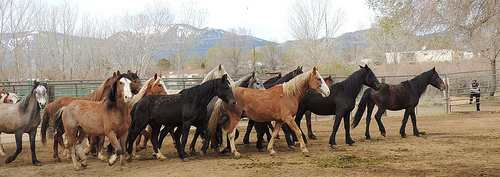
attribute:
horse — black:
[333, 60, 369, 120]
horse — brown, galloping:
[93, 84, 132, 136]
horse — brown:
[254, 64, 325, 145]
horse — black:
[406, 67, 442, 135]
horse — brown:
[54, 83, 111, 108]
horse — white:
[247, 57, 269, 89]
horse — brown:
[145, 74, 167, 96]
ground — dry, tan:
[144, 112, 491, 148]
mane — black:
[416, 74, 432, 90]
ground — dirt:
[168, 153, 240, 175]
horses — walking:
[42, 68, 482, 148]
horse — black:
[265, 73, 298, 85]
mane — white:
[132, 79, 152, 105]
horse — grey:
[0, 77, 42, 133]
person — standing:
[465, 69, 499, 109]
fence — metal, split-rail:
[445, 68, 470, 122]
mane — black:
[109, 73, 123, 106]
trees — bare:
[289, 11, 343, 73]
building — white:
[388, 41, 486, 68]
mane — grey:
[227, 71, 253, 87]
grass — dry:
[444, 110, 500, 167]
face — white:
[308, 76, 332, 95]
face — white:
[122, 75, 135, 109]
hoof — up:
[299, 142, 315, 161]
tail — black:
[351, 87, 376, 123]